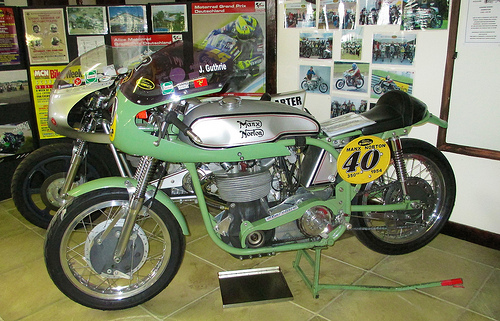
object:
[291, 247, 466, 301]
stand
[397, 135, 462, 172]
rim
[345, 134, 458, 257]
wheel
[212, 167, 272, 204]
tank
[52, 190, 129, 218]
rubing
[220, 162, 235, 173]
lid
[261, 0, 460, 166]
notice board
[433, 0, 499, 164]
edge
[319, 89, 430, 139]
seat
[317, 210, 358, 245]
pedal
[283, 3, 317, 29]
picture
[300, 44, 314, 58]
motorbikes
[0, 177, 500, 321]
floor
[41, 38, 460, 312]
bike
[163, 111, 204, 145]
gear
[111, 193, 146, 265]
tube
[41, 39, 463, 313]
motorcycle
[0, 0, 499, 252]
wall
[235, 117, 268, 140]
writing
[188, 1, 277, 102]
sign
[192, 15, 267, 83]
person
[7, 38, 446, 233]
motorcycle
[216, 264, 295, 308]
pan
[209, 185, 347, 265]
engine